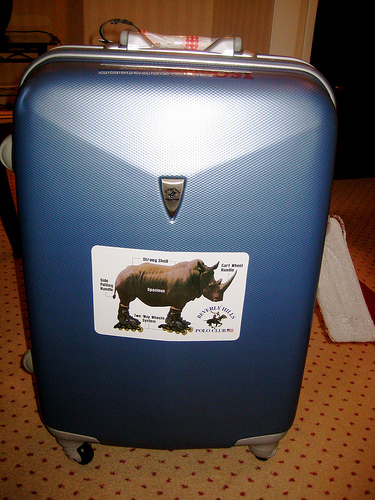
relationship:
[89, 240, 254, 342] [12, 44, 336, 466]
sticker on bag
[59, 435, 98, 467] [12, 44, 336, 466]
wheel on bag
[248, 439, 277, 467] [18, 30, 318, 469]
wheel on suitcase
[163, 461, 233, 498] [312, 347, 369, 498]
dots on carpet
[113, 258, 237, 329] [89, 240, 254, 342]
animal on sticker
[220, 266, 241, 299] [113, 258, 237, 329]
horn on animal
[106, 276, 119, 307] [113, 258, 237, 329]
tail on animal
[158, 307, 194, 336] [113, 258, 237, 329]
roller blades on animal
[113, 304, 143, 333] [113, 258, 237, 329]
roller skates on animal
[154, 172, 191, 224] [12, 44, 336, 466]
logo on bag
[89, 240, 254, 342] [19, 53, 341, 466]
sticker on luggage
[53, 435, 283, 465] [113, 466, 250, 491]
tires on floor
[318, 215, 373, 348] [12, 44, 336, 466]
cloth on side of bag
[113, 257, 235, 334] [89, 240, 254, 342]
animal on sticker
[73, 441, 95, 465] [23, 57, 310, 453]
wheel on suitcase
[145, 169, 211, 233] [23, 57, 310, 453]
thing on suitcase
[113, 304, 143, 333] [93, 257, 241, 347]
roller skates on rhino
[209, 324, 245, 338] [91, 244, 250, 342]
flag on sticker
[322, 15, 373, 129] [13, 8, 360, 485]
door in room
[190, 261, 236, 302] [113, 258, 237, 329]
head on animal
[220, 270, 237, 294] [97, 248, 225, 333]
horn on rhino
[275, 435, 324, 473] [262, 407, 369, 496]
dots on carpet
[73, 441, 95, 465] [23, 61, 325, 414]
wheel on luggage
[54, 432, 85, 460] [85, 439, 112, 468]
casing on wheel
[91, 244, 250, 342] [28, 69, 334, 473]
sticker on luggage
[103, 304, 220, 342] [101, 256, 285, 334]
roller skates on rhino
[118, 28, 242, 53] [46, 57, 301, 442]
handle on luggage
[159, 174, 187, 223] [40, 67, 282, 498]
logo on bag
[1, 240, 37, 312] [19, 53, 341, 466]
shadow behind luggage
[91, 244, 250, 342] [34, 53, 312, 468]
sticker on luggage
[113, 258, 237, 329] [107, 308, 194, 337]
animal on roller blades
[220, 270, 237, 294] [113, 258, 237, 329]
horn on animal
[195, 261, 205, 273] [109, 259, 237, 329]
ear of rhinoceros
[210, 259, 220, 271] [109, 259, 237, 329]
ear of rhinoceros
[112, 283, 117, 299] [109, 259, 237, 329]
tail of rhinoceros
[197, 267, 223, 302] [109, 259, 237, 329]
head of rhinoceros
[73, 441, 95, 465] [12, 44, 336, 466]
wheel of bag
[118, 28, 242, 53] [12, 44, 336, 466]
handle of bag